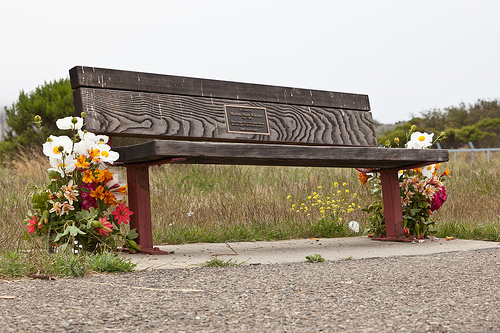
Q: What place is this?
A: It is a field.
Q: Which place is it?
A: It is a field.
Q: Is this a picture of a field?
A: Yes, it is showing a field.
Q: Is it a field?
A: Yes, it is a field.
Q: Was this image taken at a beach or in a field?
A: It was taken at a field.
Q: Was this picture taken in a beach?
A: No, the picture was taken in a field.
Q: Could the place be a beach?
A: No, it is a field.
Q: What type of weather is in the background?
A: It is clear.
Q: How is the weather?
A: It is clear.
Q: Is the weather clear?
A: Yes, it is clear.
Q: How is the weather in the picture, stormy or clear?
A: It is clear.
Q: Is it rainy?
A: No, it is clear.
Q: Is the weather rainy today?
A: No, it is clear.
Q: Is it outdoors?
A: Yes, it is outdoors.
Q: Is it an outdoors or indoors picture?
A: It is outdoors.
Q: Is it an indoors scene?
A: No, it is outdoors.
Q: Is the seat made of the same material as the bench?
A: Yes, both the seat and the bench are made of wood.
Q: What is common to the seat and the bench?
A: The material, both the seat and the bench are wooden.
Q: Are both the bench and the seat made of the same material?
A: Yes, both the bench and the seat are made of wood.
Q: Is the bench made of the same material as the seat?
A: Yes, both the bench and the seat are made of wood.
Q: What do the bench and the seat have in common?
A: The material, both the bench and the seat are wooden.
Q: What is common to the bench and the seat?
A: The material, both the bench and the seat are wooden.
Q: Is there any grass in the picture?
A: Yes, there is grass.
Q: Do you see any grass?
A: Yes, there is grass.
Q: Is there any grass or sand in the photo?
A: Yes, there is grass.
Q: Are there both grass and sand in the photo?
A: No, there is grass but no sand.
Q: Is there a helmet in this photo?
A: No, there are no helmets.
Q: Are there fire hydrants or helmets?
A: No, there are no helmets or fire hydrants.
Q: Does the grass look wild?
A: Yes, the grass is wild.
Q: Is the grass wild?
A: Yes, the grass is wild.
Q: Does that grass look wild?
A: Yes, the grass is wild.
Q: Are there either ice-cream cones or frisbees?
A: No, there are no frisbees or ice-cream cones.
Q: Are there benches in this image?
A: Yes, there is a bench.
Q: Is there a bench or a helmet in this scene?
A: Yes, there is a bench.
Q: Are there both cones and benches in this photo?
A: No, there is a bench but no cones.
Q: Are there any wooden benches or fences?
A: Yes, there is a wood bench.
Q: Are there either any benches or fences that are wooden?
A: Yes, the bench is wooden.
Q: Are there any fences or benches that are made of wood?
A: Yes, the bench is made of wood.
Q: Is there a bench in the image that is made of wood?
A: Yes, there is a bench that is made of wood.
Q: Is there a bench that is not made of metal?
A: Yes, there is a bench that is made of wood.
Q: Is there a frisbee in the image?
A: No, there are no frisbees.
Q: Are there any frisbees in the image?
A: No, there are no frisbees.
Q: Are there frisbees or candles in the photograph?
A: No, there are no frisbees or candles.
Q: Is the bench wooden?
A: Yes, the bench is wooden.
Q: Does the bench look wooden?
A: Yes, the bench is wooden.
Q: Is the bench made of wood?
A: Yes, the bench is made of wood.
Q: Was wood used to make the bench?
A: Yes, the bench is made of wood.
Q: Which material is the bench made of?
A: The bench is made of wood.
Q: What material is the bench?
A: The bench is made of wood.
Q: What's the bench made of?
A: The bench is made of wood.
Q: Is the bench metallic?
A: No, the bench is wooden.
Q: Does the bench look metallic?
A: No, the bench is wooden.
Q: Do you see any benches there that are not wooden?
A: No, there is a bench but it is wooden.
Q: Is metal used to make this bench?
A: No, the bench is made of wood.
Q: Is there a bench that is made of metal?
A: No, there is a bench but it is made of wood.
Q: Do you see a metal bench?
A: No, there is a bench but it is made of wood.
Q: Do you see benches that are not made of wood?
A: No, there is a bench but it is made of wood.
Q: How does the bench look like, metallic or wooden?
A: The bench is wooden.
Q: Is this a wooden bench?
A: Yes, this is a wooden bench.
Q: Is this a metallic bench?
A: No, this is a wooden bench.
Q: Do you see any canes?
A: No, there are no canes.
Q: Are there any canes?
A: No, there are no canes.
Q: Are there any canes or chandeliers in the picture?
A: No, there are no canes or chandeliers.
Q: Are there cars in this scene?
A: No, there are no cars.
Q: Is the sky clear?
A: Yes, the sky is clear.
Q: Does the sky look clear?
A: Yes, the sky is clear.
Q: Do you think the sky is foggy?
A: No, the sky is clear.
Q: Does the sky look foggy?
A: No, the sky is clear.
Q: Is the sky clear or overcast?
A: The sky is clear.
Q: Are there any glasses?
A: No, there are no glasses.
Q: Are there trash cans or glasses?
A: No, there are no glasses or trash cans.